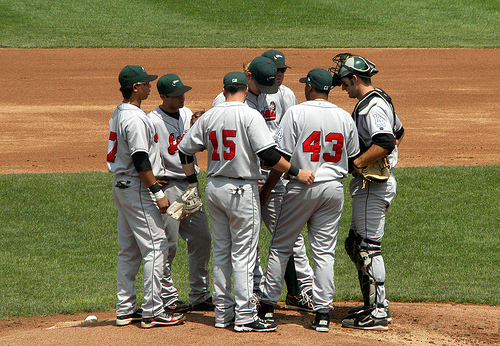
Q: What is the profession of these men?
A: Baseball players.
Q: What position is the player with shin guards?
A: Catcher.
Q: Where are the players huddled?
A: Pitcher's mound.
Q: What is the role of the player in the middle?
A: Pitcher.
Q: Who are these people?
A: Baseball players.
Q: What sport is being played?
A: Baseball.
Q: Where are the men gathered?
A: On the pitcher's mound.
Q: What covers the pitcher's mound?
A: Dirt.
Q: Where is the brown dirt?
A: Baseball field.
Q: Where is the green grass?
A: Baseball field.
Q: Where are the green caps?
A: Ballplayer's heads.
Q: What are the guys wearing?
A: Jerseys.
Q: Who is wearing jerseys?
A: Group of guys.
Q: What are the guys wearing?
A: Jerseys.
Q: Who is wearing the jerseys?
A: Group of guys.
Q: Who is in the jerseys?
A: Guys.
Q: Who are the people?
A: Baseball team.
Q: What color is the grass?
A: Green.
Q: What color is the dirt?
A: Brown.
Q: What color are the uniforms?
A: Gray.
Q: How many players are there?
A: Seven.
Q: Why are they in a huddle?
A: A timeout.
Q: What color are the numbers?
A: Red.